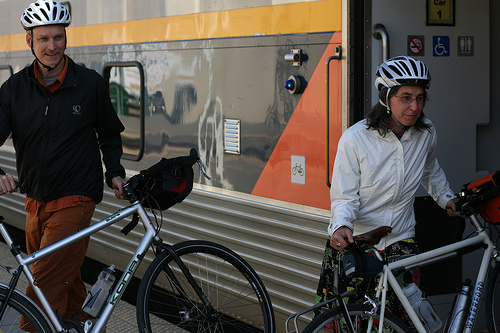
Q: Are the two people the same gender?
A: No, they are both male and female.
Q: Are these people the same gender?
A: No, they are both male and female.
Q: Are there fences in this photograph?
A: No, there are no fences.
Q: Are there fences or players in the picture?
A: No, there are no fences or players.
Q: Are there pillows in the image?
A: No, there are no pillows.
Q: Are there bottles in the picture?
A: Yes, there is a bottle.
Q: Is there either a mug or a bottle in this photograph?
A: Yes, there is a bottle.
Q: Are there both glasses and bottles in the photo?
A: Yes, there are both a bottle and glasses.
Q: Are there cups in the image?
A: No, there are no cups.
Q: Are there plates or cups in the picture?
A: No, there are no cups or plates.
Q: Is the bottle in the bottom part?
A: Yes, the bottle is in the bottom of the image.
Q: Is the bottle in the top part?
A: No, the bottle is in the bottom of the image.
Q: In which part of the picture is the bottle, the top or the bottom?
A: The bottle is in the bottom of the image.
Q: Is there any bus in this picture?
A: Yes, there is a bus.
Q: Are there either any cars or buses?
A: Yes, there is a bus.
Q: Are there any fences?
A: No, there are no fences.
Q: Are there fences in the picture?
A: No, there are no fences.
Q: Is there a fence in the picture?
A: No, there are no fences.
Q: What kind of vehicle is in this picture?
A: The vehicle is a bus.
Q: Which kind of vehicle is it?
A: The vehicle is a bus.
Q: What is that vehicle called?
A: This is a bus.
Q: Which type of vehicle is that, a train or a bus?
A: This is a bus.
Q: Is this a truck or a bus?
A: This is a bus.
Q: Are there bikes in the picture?
A: Yes, there is a bike.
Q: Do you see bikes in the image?
A: Yes, there is a bike.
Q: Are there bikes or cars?
A: Yes, there is a bike.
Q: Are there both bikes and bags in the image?
A: Yes, there are both a bike and a bag.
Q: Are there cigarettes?
A: No, there are no cigarettes.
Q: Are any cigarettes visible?
A: No, there are no cigarettes.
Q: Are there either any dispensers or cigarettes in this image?
A: No, there are no cigarettes or dispensers.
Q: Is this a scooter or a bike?
A: This is a bike.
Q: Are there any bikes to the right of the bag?
A: Yes, there is a bike to the right of the bag.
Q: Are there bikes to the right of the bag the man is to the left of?
A: Yes, there is a bike to the right of the bag.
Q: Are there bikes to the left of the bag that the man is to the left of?
A: No, the bike is to the right of the bag.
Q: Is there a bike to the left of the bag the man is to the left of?
A: No, the bike is to the right of the bag.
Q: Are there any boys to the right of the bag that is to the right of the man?
A: No, there is a bike to the right of the bag.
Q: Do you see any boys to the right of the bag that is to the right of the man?
A: No, there is a bike to the right of the bag.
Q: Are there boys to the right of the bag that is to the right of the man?
A: No, there is a bike to the right of the bag.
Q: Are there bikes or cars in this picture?
A: Yes, there is a bike.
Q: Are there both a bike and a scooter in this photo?
A: No, there is a bike but no scooters.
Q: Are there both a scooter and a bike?
A: No, there is a bike but no scooters.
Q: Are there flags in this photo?
A: No, there are no flags.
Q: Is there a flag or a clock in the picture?
A: No, there are no flags or clocks.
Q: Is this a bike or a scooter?
A: This is a bike.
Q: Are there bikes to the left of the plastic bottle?
A: Yes, there is a bike to the left of the bottle.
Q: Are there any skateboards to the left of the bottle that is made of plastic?
A: No, there is a bike to the left of the bottle.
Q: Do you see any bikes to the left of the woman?
A: Yes, there is a bike to the left of the woman.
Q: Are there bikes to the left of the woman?
A: Yes, there is a bike to the left of the woman.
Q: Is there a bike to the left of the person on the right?
A: Yes, there is a bike to the left of the woman.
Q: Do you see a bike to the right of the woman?
A: No, the bike is to the left of the woman.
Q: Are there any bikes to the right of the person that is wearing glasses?
A: No, the bike is to the left of the woman.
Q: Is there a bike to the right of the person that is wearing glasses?
A: No, the bike is to the left of the woman.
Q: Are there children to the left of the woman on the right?
A: No, there is a bike to the left of the woman.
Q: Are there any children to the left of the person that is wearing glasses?
A: No, there is a bike to the left of the woman.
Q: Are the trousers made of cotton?
A: Yes, the trousers are made of cotton.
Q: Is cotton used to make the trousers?
A: Yes, the trousers are made of cotton.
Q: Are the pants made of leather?
A: No, the pants are made of cotton.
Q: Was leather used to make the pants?
A: No, the pants are made of cotton.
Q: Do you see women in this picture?
A: Yes, there is a woman.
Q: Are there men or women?
A: Yes, there is a woman.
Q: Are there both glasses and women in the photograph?
A: Yes, there are both a woman and glasses.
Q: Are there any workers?
A: No, there are no workers.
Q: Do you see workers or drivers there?
A: No, there are no workers or drivers.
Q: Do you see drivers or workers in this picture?
A: No, there are no workers or drivers.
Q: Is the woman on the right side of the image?
A: Yes, the woman is on the right of the image.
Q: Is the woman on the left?
A: No, the woman is on the right of the image.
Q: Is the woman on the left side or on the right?
A: The woman is on the right of the image.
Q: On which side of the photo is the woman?
A: The woman is on the right of the image.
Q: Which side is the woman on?
A: The woman is on the right of the image.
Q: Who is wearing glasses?
A: The woman is wearing glasses.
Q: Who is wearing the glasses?
A: The woman is wearing glasses.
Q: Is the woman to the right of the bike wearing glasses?
A: Yes, the woman is wearing glasses.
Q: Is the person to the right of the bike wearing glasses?
A: Yes, the woman is wearing glasses.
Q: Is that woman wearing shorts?
A: No, the woman is wearing glasses.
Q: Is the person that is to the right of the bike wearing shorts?
A: No, the woman is wearing glasses.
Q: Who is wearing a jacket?
A: The woman is wearing a jacket.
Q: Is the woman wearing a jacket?
A: Yes, the woman is wearing a jacket.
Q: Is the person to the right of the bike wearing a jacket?
A: Yes, the woman is wearing a jacket.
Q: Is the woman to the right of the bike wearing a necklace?
A: No, the woman is wearing a jacket.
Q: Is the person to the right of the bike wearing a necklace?
A: No, the woman is wearing a jacket.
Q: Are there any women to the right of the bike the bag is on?
A: Yes, there is a woman to the right of the bike.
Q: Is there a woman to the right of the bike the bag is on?
A: Yes, there is a woman to the right of the bike.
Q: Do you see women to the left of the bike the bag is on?
A: No, the woman is to the right of the bike.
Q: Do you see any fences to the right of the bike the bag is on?
A: No, there is a woman to the right of the bike.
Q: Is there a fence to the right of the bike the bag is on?
A: No, there is a woman to the right of the bike.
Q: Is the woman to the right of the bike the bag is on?
A: Yes, the woman is to the right of the bike.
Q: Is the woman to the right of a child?
A: No, the woman is to the right of the bike.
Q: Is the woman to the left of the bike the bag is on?
A: No, the woman is to the right of the bike.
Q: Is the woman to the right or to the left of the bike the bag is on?
A: The woman is to the right of the bike.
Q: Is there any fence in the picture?
A: No, there are no fences.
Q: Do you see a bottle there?
A: Yes, there is a bottle.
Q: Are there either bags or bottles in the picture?
A: Yes, there is a bottle.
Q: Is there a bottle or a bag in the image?
A: Yes, there is a bottle.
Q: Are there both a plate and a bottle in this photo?
A: No, there is a bottle but no plates.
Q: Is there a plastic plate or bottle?
A: Yes, there is a plastic bottle.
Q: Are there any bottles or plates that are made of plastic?
A: Yes, the bottle is made of plastic.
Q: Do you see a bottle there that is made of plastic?
A: Yes, there is a bottle that is made of plastic.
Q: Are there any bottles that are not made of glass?
A: Yes, there is a bottle that is made of plastic.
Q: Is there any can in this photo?
A: No, there are no cans.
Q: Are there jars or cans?
A: No, there are no cans or jars.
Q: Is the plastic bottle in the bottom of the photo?
A: Yes, the bottle is in the bottom of the image.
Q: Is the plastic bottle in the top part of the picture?
A: No, the bottle is in the bottom of the image.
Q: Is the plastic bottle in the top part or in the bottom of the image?
A: The bottle is in the bottom of the image.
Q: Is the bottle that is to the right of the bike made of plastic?
A: Yes, the bottle is made of plastic.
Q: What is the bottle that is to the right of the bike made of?
A: The bottle is made of plastic.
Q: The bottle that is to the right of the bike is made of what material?
A: The bottle is made of plastic.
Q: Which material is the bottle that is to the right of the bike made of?
A: The bottle is made of plastic.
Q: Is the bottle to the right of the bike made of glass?
A: No, the bottle is made of plastic.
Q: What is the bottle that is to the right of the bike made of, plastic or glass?
A: The bottle is made of plastic.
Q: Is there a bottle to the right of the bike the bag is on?
A: Yes, there is a bottle to the right of the bike.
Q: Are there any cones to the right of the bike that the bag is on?
A: No, there is a bottle to the right of the bike.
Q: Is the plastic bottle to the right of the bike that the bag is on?
A: Yes, the bottle is to the right of the bike.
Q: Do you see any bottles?
A: Yes, there is a bottle.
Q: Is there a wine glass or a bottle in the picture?
A: Yes, there is a bottle.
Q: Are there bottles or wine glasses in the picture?
A: Yes, there is a bottle.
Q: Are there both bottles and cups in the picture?
A: No, there is a bottle but no cups.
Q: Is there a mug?
A: No, there are no mugs.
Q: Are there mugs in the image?
A: No, there are no mugs.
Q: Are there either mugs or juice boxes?
A: No, there are no mugs or juice boxes.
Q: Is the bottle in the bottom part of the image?
A: Yes, the bottle is in the bottom of the image.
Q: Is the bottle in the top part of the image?
A: No, the bottle is in the bottom of the image.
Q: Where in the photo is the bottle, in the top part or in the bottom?
A: The bottle is in the bottom of the image.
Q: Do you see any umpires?
A: No, there are no umpires.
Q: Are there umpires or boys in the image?
A: No, there are no umpires or boys.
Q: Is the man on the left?
A: Yes, the man is on the left of the image.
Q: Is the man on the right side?
A: No, the man is on the left of the image.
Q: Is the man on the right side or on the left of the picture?
A: The man is on the left of the image.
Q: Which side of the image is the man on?
A: The man is on the left of the image.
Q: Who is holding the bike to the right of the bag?
A: The man is holding the bike.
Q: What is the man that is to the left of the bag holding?
A: The man is holding the bike.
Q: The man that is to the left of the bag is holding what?
A: The man is holding the bike.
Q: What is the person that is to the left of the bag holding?
A: The man is holding the bike.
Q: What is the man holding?
A: The man is holding the bike.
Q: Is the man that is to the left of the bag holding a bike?
A: Yes, the man is holding a bike.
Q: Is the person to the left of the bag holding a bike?
A: Yes, the man is holding a bike.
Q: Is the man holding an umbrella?
A: No, the man is holding a bike.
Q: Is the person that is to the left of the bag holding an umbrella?
A: No, the man is holding a bike.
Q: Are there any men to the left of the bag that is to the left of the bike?
A: Yes, there is a man to the left of the bag.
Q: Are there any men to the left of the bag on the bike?
A: Yes, there is a man to the left of the bag.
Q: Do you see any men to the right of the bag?
A: No, the man is to the left of the bag.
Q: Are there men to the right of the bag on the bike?
A: No, the man is to the left of the bag.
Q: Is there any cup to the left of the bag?
A: No, there is a man to the left of the bag.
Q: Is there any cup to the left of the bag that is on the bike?
A: No, there is a man to the left of the bag.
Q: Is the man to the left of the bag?
A: Yes, the man is to the left of the bag.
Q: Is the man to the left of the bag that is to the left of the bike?
A: Yes, the man is to the left of the bag.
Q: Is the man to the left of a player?
A: No, the man is to the left of the bag.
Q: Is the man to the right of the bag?
A: No, the man is to the left of the bag.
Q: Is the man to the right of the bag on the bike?
A: No, the man is to the left of the bag.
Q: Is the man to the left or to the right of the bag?
A: The man is to the left of the bag.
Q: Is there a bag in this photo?
A: Yes, there is a bag.